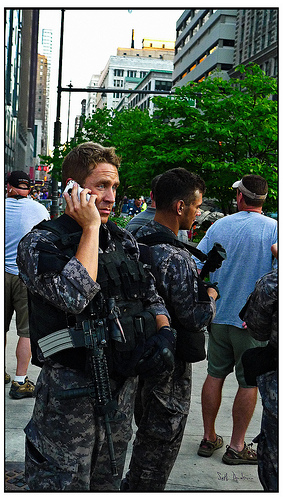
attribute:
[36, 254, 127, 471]
guns — large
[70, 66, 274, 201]
leaves — green, bright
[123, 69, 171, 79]
roof — green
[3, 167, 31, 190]
cap — black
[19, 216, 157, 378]
vest — bulletproof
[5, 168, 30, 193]
baseball hat — black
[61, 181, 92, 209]
phone — silver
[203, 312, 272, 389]
shorts — green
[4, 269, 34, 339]
shorts — brown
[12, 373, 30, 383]
sock — white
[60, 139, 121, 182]
hair — light brown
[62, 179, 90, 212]
cellphone — white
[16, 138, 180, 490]
soldier — male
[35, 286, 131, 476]
weapon — military, large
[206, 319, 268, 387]
shorts — green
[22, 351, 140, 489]
pants — camouflage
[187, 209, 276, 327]
shirt — gray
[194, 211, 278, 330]
shirt — gray